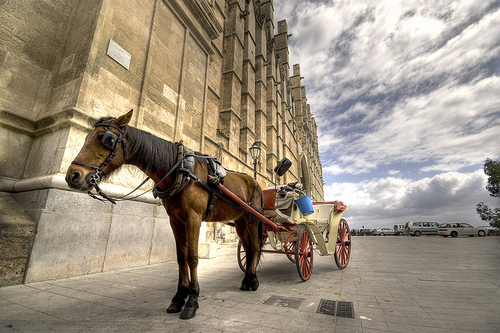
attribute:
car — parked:
[391, 210, 455, 243]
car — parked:
[436, 221, 491, 241]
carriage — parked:
[253, 161, 360, 274]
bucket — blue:
[291, 191, 317, 221]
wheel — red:
[291, 228, 317, 281]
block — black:
[98, 130, 122, 150]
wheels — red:
[291, 233, 327, 283]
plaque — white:
[62, 26, 193, 98]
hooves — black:
[166, 290, 198, 317]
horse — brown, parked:
[64, 108, 263, 318]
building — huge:
[8, 10, 410, 259]